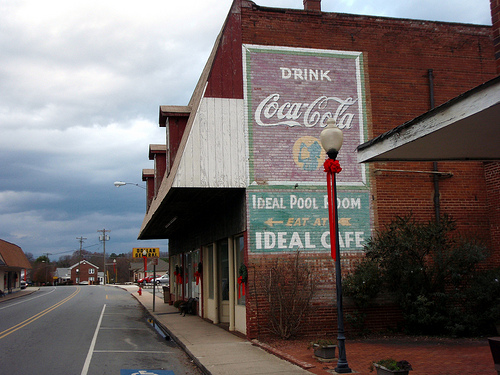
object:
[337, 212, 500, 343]
tree bush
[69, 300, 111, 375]
line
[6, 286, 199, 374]
street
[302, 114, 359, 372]
light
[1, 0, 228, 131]
clouds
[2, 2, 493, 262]
sky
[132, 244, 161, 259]
sign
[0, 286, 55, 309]
lines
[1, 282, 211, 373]
road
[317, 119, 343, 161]
lamp cover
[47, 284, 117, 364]
girl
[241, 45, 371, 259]
advertisement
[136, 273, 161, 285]
vehicles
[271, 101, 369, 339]
bow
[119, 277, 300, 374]
sidewalk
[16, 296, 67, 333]
line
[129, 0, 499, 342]
building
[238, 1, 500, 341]
wall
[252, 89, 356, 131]
coca-cola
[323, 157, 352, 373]
pole